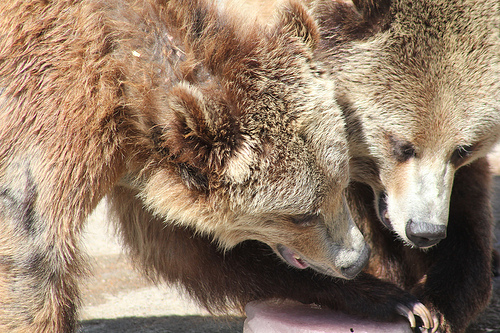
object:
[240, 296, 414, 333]
object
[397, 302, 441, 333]
claws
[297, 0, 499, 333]
bear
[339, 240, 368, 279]
nose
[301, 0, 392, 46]
ear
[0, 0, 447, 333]
bear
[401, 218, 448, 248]
nose